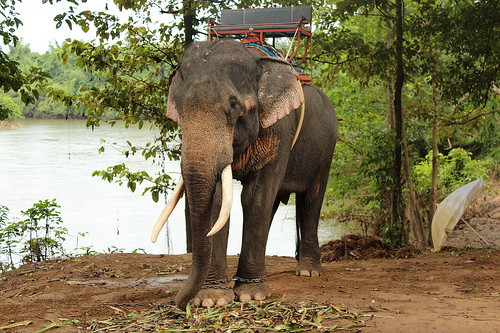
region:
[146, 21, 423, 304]
an elephant beside a river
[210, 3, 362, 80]
seat on top of the elephant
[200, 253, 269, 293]
elephant chained by the legs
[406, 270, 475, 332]
floor is rugged muddy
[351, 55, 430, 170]
plants rare green yellow in color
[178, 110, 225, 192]
elephant nostril is brown in color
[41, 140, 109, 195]
water is colorles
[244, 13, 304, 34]
seat is black in color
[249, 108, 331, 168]
lephant is black in color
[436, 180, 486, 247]
umbrela is white in color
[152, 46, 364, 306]
A big grey elephant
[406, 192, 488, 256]
A small white umbrella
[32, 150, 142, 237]
A still dirty water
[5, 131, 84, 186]
A still dirty water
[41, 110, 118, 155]
A still dirty water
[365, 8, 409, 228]
A small tall tree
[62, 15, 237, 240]
A small tall tree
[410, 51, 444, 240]
A small tall tree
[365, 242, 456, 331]
A brown sandy ground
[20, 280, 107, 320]
A brown sandy ground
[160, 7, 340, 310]
Elephant with a bench on its back.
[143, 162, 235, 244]
Large white elephant tusks.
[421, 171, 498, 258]
White and yellow umbrella sitting on the ground.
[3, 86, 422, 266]
Dirty river surrounded by trees.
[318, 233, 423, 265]
Mound of grassy dirt.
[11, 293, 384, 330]
Small pile of tree leaves.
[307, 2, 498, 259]
A group of thick trees beside a river.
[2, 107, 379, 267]
River flowing through a forest.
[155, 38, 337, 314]
Grey elephant with large white tusks.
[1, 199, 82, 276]
Baby trees beside a flowing river.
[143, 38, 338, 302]
the elephant is standing still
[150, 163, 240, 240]
the elephant has two tusks in front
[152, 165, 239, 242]
the tusks are white in color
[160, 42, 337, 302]
the elephant is brown in color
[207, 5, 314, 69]
a chair is on top of the elephant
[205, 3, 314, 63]
the chair is long in size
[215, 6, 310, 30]
the cushions are grey in color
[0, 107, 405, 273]
a river is behind the elephant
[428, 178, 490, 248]
an umbrella is on the ground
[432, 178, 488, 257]
the umbrella is white in color